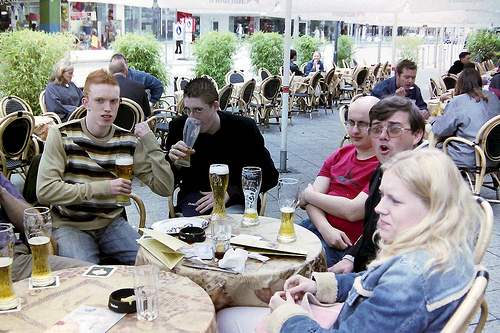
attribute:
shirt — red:
[325, 145, 362, 248]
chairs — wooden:
[212, 70, 278, 114]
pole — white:
[272, 17, 305, 145]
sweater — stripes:
[43, 126, 156, 262]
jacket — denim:
[343, 255, 428, 331]